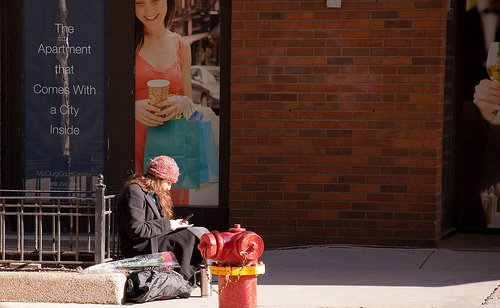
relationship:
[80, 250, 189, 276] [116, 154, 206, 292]
bouquet of roses lying next to girl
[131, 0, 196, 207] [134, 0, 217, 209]
woman shown on sign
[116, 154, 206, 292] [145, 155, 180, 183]
girl wearing beanie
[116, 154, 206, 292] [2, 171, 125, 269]
girl sitting against fence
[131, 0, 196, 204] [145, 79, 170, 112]
woman holding cup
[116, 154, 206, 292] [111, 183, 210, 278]
girl wearing black coat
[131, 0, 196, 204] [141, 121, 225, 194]
woman holding blue shopping bag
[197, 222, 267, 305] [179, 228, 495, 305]
fire hydrant standing on sidewalk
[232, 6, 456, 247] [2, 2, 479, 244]
brick wall standing in background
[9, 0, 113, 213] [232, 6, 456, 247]
apartment advert hung near brick wall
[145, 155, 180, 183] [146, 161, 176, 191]
beanie covering head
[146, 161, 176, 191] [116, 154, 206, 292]
head belonging to girl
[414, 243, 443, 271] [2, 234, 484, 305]
crack on the appearing in sidewalk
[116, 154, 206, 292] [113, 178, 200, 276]
girl wearing coat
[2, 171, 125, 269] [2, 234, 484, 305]
fence standing alongside sidewalk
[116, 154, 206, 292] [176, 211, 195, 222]
girl holding cell phone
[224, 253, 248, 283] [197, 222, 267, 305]
chain hanging from fire hydrant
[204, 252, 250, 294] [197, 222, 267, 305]
chain hanging from fire hydrant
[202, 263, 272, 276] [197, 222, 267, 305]
yellow strip painted on fire hydrant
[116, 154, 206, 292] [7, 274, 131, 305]
girl sitting on curbside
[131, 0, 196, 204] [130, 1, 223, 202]
woman featured on poster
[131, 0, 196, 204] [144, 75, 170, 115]
woman holding coffee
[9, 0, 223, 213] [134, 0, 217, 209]
apartment advert featured on sign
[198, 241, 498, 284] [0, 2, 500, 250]
shadow from building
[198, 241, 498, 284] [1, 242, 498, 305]
shadow on ground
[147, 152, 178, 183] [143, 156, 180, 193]
beanie on head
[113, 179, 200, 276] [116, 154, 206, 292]
coat on girl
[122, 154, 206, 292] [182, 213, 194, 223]
girl holding cell phone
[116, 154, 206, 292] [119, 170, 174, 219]
girl with brown hair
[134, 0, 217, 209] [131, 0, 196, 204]
sign with woman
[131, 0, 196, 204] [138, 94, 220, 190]
woman holding bags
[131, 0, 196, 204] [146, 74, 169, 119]
woman with cup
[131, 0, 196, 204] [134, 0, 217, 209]
woman on sign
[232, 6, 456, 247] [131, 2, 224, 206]
brick wall beside sign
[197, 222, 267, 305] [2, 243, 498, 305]
fire hydrant by sidewalk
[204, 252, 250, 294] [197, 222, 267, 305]
chain on fire hydrant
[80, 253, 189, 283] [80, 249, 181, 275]
bouquet of roses in plastic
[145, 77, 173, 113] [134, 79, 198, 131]
cup in woman's hand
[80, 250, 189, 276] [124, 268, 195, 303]
bouquet of roses resting on black back pack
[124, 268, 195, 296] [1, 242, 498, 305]
black back pack on ground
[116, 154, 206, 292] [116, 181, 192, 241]
girl has right arm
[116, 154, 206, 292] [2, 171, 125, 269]
girl leaning against fence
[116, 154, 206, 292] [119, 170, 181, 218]
girl has brown hair